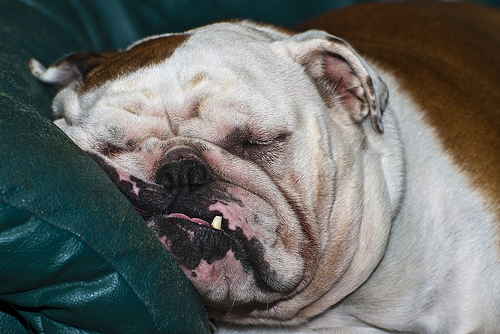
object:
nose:
[39, 36, 499, 328]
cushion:
[4, 1, 174, 332]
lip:
[172, 196, 294, 293]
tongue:
[162, 211, 213, 227]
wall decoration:
[55, 24, 386, 269]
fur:
[408, 43, 468, 99]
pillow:
[1, 0, 356, 333]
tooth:
[210, 215, 222, 227]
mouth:
[131, 190, 306, 295]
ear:
[279, 24, 395, 130]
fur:
[394, 196, 495, 318]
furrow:
[99, 62, 226, 147]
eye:
[233, 128, 295, 165]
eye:
[98, 137, 136, 157]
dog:
[64, 20, 473, 331]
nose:
[135, 141, 242, 213]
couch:
[5, 1, 214, 331]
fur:
[369, 60, 484, 301]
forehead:
[54, 65, 329, 135]